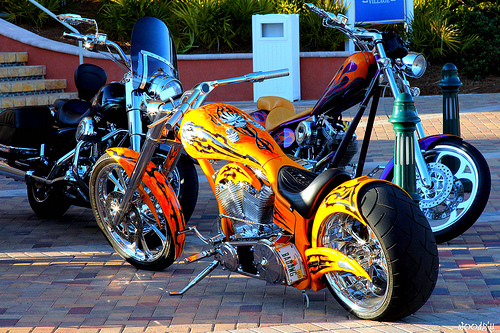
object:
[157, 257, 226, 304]
kickstand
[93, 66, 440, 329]
motorcycle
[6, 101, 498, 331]
pavement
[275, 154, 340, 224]
seat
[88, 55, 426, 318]
motorcycle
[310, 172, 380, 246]
fender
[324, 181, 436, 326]
tire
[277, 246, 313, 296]
license plate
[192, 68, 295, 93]
handlebar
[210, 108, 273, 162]
design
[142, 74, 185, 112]
light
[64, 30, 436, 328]
motorcycle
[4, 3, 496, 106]
trees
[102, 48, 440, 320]
motorcycle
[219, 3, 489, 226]
motorcycle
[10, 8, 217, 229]
motorcycle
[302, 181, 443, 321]
tire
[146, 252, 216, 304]
kickstand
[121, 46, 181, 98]
windshield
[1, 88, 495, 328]
ground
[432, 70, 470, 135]
pole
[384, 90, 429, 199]
pole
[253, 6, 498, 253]
motorcycle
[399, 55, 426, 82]
headlight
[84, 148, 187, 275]
front tire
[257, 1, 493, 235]
motorcycle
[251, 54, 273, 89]
post box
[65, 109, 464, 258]
background